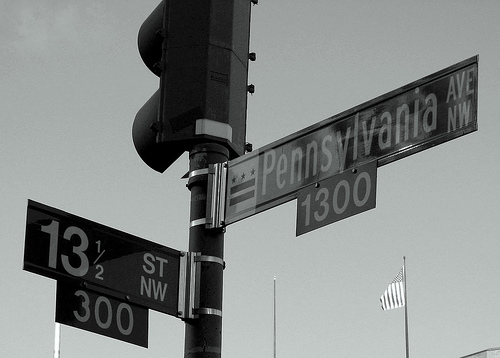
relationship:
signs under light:
[13, 45, 499, 345] [124, 3, 254, 171]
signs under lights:
[13, 45, 499, 345] [118, 4, 256, 172]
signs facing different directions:
[13, 45, 499, 345] [7, 43, 490, 355]